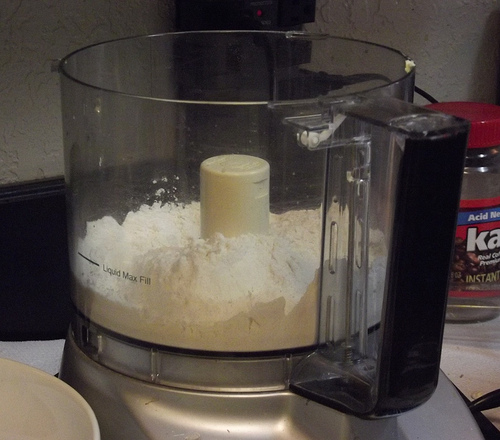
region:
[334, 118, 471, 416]
a black plastic handle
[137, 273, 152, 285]
the word fill in black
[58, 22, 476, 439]
white flour in a food processer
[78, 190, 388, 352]
white flour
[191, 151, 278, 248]
the center of a food processer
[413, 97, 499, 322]
an emtpy glass jar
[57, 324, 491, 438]
the base of a food processer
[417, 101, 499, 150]
the red top of a jar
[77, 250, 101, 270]
a black line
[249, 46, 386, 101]
a black plug plugged into a wall socket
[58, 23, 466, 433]
white flour in blender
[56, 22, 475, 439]
white flour in mixer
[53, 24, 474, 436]
white powder in mixer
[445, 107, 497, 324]
bottle with red label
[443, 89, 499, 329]
bottle of karo syrup behind blender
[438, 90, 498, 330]
bottle on counter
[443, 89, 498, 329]
bottle with red top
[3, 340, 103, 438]
cream colored bowl next to blender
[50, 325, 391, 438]
bottom of mixer is gray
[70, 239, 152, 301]
black mark on blender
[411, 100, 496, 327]
Instant coffe jar, clear with red lid and label, label also has coffee beans picture on it amongst other things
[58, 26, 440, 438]
open blender with white powder, possibly flour, inside it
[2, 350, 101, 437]
portion of a white round ceramic dish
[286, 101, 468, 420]
black blender handle on clear blender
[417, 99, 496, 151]
round red jar lid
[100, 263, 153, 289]
black letter on clear blender that read Liquid Max Fill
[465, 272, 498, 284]
yellow letters on brown background that read INSTANT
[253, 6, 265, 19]
round red button on a black surface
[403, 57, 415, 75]
blotch of something yellowish on the edge of a blender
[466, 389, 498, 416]
piece of black electric cording from a blender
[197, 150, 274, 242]
the center of a mixing machine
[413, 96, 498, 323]
an empty plastic jar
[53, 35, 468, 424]
a blender filled with flour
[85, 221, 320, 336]
flour in a blender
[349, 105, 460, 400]
a black handle to a blender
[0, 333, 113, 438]
a white mug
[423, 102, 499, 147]
a red twist off cap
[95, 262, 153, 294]
writing on a blender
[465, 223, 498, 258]
writing on a jar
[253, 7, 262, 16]
an unlit red light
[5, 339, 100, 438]
ivory bowl next to blender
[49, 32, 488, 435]
blender with flour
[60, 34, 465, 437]
blender with silver bottom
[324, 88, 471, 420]
black handle on blender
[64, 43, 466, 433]
blender with black handle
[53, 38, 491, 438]
mixer on counter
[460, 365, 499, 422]
cord to mixer on counter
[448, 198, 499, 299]
blue, red and white label on bottle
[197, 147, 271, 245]
attachment in center of mixer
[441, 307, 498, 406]
white counter